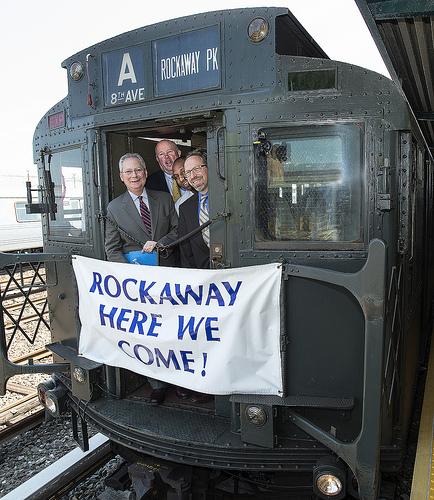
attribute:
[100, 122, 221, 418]
doorway — open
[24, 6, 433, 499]
train — silver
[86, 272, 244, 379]
words — blue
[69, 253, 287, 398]
banner — white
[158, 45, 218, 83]
words — rockway pk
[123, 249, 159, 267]
folder — blue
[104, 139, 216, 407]
people — posing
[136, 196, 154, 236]
tie — red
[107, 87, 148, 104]
words — 8th ave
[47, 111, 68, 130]
exp sign — red